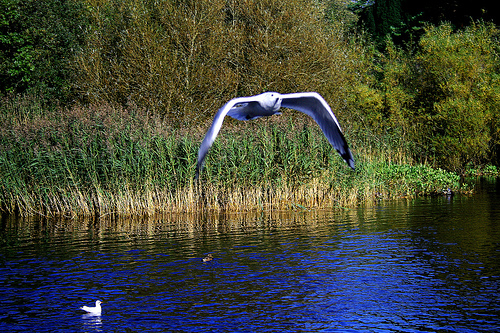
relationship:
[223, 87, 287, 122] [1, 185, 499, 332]
bird flying above water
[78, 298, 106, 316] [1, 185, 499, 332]
bird floating water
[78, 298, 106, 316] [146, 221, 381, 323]
bird in water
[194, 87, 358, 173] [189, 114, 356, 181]
bird has wings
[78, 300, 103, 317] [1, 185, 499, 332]
bird in water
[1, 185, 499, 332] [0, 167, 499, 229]
water on shoreline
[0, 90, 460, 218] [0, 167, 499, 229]
brush on shoreline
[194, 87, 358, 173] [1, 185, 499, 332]
bird above water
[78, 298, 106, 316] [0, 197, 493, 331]
bird swimming in water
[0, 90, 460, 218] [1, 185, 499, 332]
brush in water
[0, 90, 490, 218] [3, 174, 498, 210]
brush on shoreline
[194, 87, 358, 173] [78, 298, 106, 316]
bird above bird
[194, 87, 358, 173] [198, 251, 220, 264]
bird above birds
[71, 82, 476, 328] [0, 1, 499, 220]
birds at shoreline